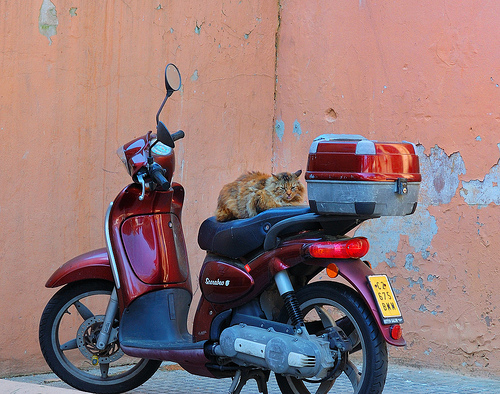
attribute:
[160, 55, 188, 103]
mirror — motorcycle, rear view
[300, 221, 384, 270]
light — tail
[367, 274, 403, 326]
plate — black, yellow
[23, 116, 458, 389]
scooter — red, parked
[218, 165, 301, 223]
cat — resting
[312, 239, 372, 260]
light — red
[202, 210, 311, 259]
seat — black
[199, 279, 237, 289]
lettering — white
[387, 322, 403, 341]
circle — red